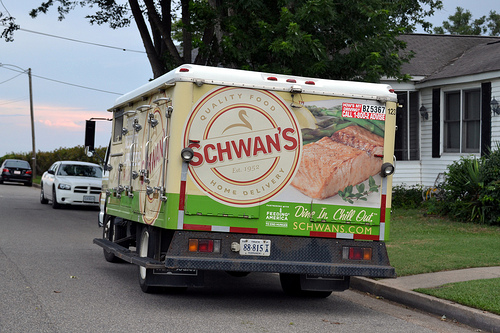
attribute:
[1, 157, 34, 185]
car — parked, small, black, sedan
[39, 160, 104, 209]
car — parked, white, small, sedan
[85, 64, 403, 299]
truck — medium-sized, yellow with green, food delivery, parked, schwan's, refrigerated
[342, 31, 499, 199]
house — white, wooden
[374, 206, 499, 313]
grass — green, neatly cut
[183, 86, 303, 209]
logo — big, round, cicular, schwan's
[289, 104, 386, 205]
picture — food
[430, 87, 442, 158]
shutter — black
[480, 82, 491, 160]
shutter — black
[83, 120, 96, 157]
mirror — rear-view, side view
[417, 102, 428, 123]
lamp — black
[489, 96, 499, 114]
lamp — black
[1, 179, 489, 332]
road — gray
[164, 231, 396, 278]
bumper — black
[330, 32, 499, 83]
roof — brown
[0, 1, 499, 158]
sky — blue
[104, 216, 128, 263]
tire — black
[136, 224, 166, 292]
tire — black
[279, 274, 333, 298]
tire — black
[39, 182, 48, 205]
tire — black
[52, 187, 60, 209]
tire — black